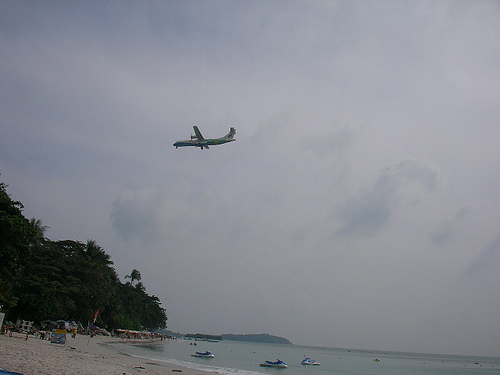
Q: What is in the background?
A: Water.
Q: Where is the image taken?
A: Beach.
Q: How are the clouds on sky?
A: Wispy.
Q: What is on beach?
A: Tall green trees.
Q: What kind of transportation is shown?
A: Airplane.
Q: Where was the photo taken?
A: Beach.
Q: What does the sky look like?
A: Overcast and dark.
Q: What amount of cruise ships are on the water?
A: 0.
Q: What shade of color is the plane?
A: White.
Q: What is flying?
A: Plane.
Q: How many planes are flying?
A: One.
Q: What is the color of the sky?
A: Gray.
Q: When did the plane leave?
A: This morning.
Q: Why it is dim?
A: It's gloomy day.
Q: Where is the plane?
A: Flying.